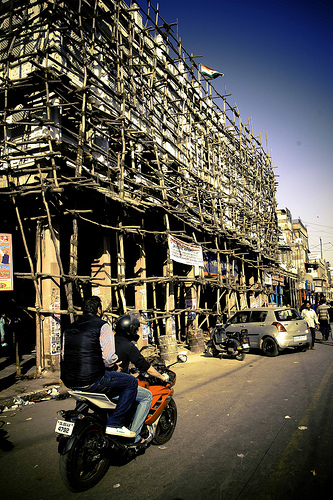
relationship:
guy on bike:
[60, 294, 136, 438] [56, 352, 186, 491]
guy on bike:
[107, 316, 169, 449] [56, 352, 186, 491]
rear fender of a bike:
[56, 414, 102, 455] [56, 352, 186, 491]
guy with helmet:
[107, 316, 169, 449] [113, 315, 140, 341]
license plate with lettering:
[54, 418, 74, 437] [57, 423, 69, 433]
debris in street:
[230, 413, 305, 464] [0, 319, 331, 497]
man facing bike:
[300, 301, 316, 351] [56, 352, 186, 491]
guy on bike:
[56, 294, 137, 441] [56, 352, 186, 491]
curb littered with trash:
[1, 384, 62, 415] [4, 383, 64, 414]